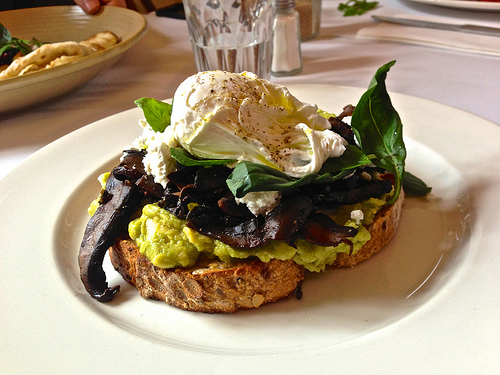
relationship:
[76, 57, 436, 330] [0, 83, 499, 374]
sandwhich on plate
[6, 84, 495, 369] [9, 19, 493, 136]
plate on table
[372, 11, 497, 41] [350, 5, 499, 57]
silverware on white napkin